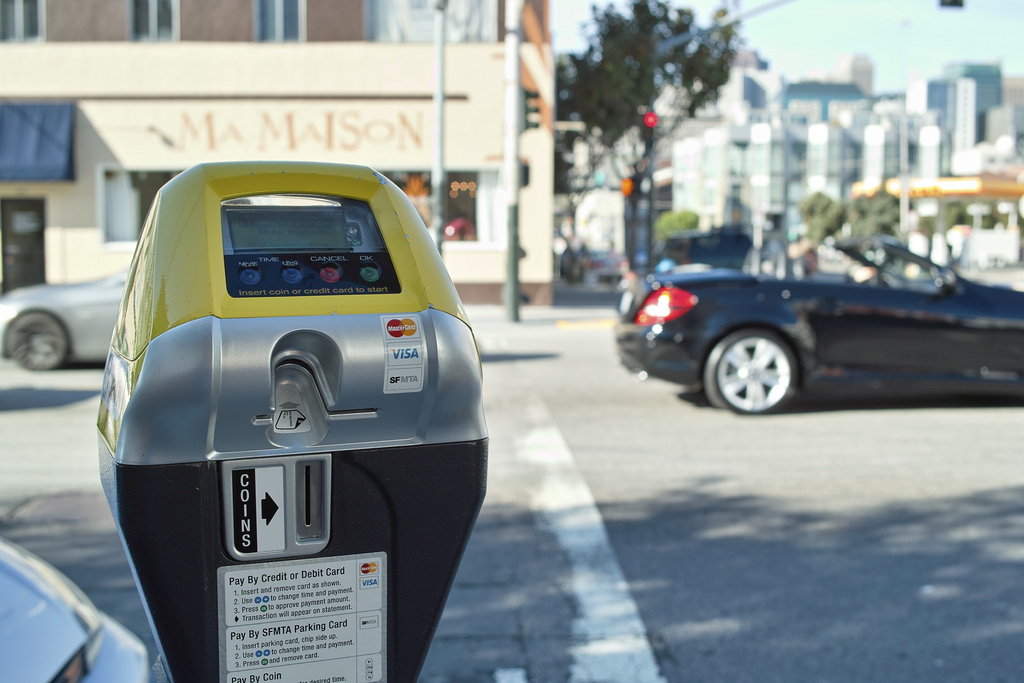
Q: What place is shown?
A: It is a street.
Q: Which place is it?
A: It is a street.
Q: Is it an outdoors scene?
A: Yes, it is outdoors.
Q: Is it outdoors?
A: Yes, it is outdoors.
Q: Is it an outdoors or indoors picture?
A: It is outdoors.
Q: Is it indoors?
A: No, it is outdoors.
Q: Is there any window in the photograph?
A: Yes, there is a window.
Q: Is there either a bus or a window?
A: Yes, there is a window.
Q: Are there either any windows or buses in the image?
A: Yes, there is a window.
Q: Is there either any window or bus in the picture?
A: Yes, there is a window.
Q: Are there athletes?
A: No, there are no athletes.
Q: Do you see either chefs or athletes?
A: No, there are no athletes or chefs.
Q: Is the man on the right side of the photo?
A: Yes, the man is on the right of the image.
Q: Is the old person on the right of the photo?
A: Yes, the man is on the right of the image.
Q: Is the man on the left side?
A: No, the man is on the right of the image.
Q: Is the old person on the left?
A: No, the man is on the right of the image.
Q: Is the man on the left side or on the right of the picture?
A: The man is on the right of the image.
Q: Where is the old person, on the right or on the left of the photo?
A: The man is on the right of the image.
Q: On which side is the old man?
A: The man is on the right of the image.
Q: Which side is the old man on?
A: The man is on the right of the image.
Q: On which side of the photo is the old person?
A: The man is on the right of the image.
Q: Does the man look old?
A: Yes, the man is old.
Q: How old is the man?
A: The man is old.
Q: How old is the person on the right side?
A: The man is old.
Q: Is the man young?
A: No, the man is old.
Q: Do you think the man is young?
A: No, the man is old.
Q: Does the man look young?
A: No, the man is old.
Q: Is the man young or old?
A: The man is old.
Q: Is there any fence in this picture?
A: No, there are no fences.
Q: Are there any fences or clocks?
A: No, there are no fences or clocks.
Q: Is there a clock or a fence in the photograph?
A: No, there are no fences or clocks.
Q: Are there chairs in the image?
A: No, there are no chairs.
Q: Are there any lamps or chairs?
A: No, there are no chairs or lamps.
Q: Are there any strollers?
A: No, there are no strollers.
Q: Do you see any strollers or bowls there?
A: No, there are no strollers or bowls.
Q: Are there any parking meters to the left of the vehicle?
A: Yes, there is a parking meter to the left of the vehicle.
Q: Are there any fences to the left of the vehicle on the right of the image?
A: No, there is a parking meter to the left of the vehicle.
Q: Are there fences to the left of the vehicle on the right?
A: No, there is a parking meter to the left of the vehicle.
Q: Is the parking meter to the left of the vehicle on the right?
A: Yes, the parking meter is to the left of the vehicle.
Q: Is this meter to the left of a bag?
A: No, the meter is to the left of the vehicle.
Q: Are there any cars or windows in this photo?
A: Yes, there is a window.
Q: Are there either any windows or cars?
A: Yes, there is a window.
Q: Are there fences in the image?
A: No, there are no fences.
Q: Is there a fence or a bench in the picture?
A: No, there are no fences or benches.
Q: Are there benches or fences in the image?
A: No, there are no fences or benches.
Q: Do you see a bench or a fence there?
A: No, there are no fences or benches.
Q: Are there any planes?
A: No, there are no planes.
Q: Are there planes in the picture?
A: No, there are no planes.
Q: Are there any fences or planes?
A: No, there are no planes or fences.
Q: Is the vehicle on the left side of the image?
A: No, the vehicle is on the right of the image.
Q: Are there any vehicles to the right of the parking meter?
A: Yes, there is a vehicle to the right of the parking meter.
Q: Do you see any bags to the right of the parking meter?
A: No, there is a vehicle to the right of the parking meter.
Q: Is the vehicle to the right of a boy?
A: No, the vehicle is to the right of the meter.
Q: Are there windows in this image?
A: Yes, there is a window.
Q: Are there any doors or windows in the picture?
A: Yes, there is a window.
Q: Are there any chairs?
A: No, there are no chairs.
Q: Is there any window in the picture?
A: Yes, there is a window.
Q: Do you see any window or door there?
A: Yes, there is a window.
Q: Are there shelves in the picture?
A: No, there are no shelves.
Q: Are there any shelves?
A: No, there are no shelves.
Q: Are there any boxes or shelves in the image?
A: No, there are no shelves or boxes.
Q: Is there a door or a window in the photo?
A: Yes, there is a window.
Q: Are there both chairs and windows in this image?
A: No, there is a window but no chairs.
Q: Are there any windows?
A: Yes, there is a window.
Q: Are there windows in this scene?
A: Yes, there is a window.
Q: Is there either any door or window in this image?
A: Yes, there is a window.